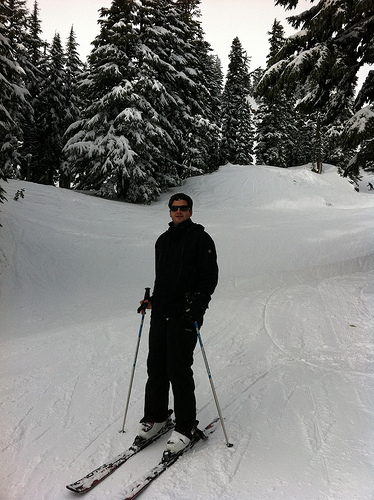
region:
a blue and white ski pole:
[182, 289, 241, 451]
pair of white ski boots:
[131, 406, 198, 456]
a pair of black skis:
[55, 414, 225, 492]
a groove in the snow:
[258, 275, 285, 354]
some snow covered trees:
[0, 6, 367, 221]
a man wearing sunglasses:
[161, 190, 204, 221]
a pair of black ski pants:
[133, 303, 214, 434]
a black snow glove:
[184, 291, 213, 328]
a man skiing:
[115, 166, 332, 494]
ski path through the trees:
[32, 72, 357, 418]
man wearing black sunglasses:
[166, 202, 192, 212]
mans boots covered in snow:
[163, 429, 192, 454]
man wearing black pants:
[139, 309, 202, 430]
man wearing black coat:
[147, 221, 221, 321]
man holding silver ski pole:
[117, 285, 150, 431]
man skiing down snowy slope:
[136, 190, 220, 453]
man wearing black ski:
[65, 416, 178, 495]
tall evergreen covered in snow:
[63, 0, 220, 209]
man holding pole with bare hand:
[138, 295, 153, 314]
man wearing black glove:
[185, 296, 207, 329]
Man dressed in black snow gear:
[124, 183, 234, 481]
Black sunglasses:
[167, 204, 193, 213]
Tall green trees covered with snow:
[71, 1, 347, 185]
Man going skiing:
[59, 199, 263, 484]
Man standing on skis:
[98, 157, 315, 467]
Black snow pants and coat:
[147, 223, 205, 435]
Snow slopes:
[215, 167, 341, 303]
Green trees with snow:
[13, 6, 371, 181]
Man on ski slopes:
[22, 164, 284, 498]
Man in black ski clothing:
[52, 193, 222, 463]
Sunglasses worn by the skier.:
[168, 203, 191, 212]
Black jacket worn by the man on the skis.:
[158, 223, 218, 286]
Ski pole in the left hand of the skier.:
[121, 287, 153, 433]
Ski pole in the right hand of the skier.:
[194, 302, 239, 452]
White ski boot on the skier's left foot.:
[139, 417, 163, 441]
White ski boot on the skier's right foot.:
[162, 419, 196, 453]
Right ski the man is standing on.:
[126, 435, 200, 499]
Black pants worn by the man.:
[141, 310, 200, 438]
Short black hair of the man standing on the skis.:
[161, 190, 196, 212]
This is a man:
[110, 181, 255, 464]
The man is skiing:
[110, 170, 253, 469]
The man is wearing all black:
[126, 176, 262, 477]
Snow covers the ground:
[76, 190, 344, 447]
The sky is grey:
[51, 10, 350, 193]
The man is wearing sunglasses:
[142, 183, 246, 292]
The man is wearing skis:
[102, 217, 269, 496]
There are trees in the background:
[84, 9, 292, 202]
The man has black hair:
[158, 170, 206, 250]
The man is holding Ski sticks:
[112, 256, 276, 449]